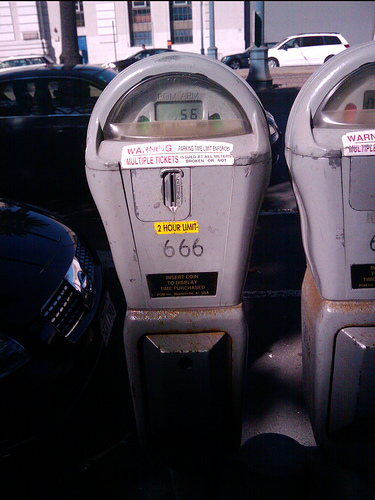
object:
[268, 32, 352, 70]
car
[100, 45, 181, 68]
car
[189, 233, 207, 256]
number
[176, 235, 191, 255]
number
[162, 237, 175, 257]
number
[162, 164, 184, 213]
coin slot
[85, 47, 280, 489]
parking meter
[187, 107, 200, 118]
number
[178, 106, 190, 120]
number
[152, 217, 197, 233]
sticker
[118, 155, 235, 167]
sticker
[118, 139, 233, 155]
sticker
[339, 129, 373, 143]
sticker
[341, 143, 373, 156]
sticker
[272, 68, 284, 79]
road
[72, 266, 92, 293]
emblem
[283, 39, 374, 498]
parking meter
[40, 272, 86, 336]
grill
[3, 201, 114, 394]
car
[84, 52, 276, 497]
machine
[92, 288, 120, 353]
plate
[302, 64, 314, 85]
road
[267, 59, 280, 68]
wheel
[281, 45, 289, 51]
side mirror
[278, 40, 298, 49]
window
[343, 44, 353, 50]
indicator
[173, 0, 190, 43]
window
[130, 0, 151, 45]
window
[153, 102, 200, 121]
display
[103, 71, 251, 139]
cover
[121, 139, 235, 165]
words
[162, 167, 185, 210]
slot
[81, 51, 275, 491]
meter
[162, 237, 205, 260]
numbers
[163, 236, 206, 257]
666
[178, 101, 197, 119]
56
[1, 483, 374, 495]
bottom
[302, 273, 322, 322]
rust